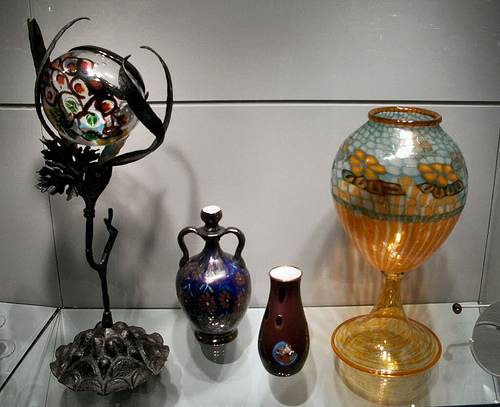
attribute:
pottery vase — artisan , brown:
[261, 250, 315, 381]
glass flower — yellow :
[337, 141, 391, 193]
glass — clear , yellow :
[332, 115, 462, 286]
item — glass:
[322, 107, 472, 402]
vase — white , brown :
[266, 267, 313, 378]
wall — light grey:
[207, 33, 320, 184]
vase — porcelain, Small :
[256, 256, 315, 381]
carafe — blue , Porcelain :
[165, 200, 260, 351]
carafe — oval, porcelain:
[166, 198, 250, 344]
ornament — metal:
[24, 3, 181, 393]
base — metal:
[47, 309, 174, 405]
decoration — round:
[38, 45, 139, 148]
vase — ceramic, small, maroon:
[258, 254, 312, 376]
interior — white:
[265, 263, 303, 284]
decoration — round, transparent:
[42, 33, 144, 142]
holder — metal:
[16, 3, 176, 404]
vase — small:
[255, 263, 311, 377]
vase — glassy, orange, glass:
[329, 104, 470, 377]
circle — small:
[270, 338, 297, 368]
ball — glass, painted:
[37, 47, 147, 147]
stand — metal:
[24, 14, 174, 396]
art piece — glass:
[25, 13, 175, 396]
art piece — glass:
[174, 202, 252, 346]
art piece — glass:
[255, 263, 312, 376]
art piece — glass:
[327, 103, 469, 378]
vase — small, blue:
[173, 203, 252, 346]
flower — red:
[196, 290, 218, 315]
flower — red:
[217, 288, 233, 312]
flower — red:
[231, 265, 248, 287]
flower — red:
[231, 290, 247, 318]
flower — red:
[176, 290, 196, 310]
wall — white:
[1, 0, 498, 308]